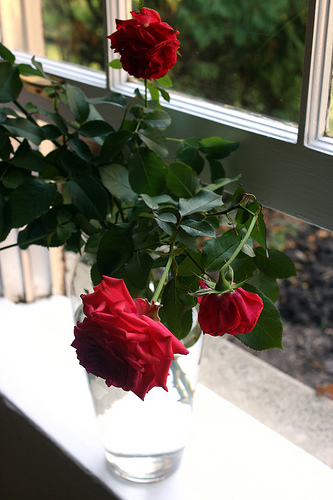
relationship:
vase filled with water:
[71, 237, 207, 486] [74, 308, 203, 486]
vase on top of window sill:
[71, 237, 207, 486] [5, 286, 332, 499]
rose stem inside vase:
[169, 355, 194, 410] [71, 237, 207, 486]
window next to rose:
[4, 2, 328, 466] [111, 11, 188, 83]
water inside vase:
[74, 308, 203, 486] [71, 237, 207, 486]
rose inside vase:
[111, 11, 188, 83] [71, 237, 207, 486]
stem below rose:
[151, 225, 181, 302] [111, 11, 188, 83]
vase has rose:
[71, 237, 207, 486] [111, 11, 188, 83]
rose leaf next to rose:
[97, 163, 140, 201] [111, 11, 188, 83]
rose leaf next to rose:
[64, 81, 90, 123] [111, 11, 188, 83]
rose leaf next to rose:
[164, 161, 196, 201] [111, 11, 188, 83]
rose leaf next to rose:
[200, 135, 239, 159] [111, 11, 188, 83]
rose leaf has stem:
[64, 81, 90, 123] [55, 89, 69, 150]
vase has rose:
[71, 237, 207, 486] [68, 280, 181, 394]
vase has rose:
[71, 237, 207, 486] [196, 280, 261, 333]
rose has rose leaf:
[111, 11, 188, 83] [64, 81, 90, 123]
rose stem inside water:
[169, 355, 194, 410] [74, 308, 203, 486]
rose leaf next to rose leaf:
[10, 182, 65, 224] [97, 163, 140, 201]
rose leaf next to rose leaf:
[164, 161, 196, 201] [200, 135, 239, 159]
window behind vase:
[4, 2, 328, 466] [71, 237, 207, 486]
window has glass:
[4, 2, 328, 466] [1, 2, 314, 136]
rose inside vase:
[68, 280, 181, 394] [71, 237, 207, 486]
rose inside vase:
[196, 280, 261, 333] [71, 237, 207, 486]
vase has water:
[71, 237, 207, 486] [74, 308, 203, 486]